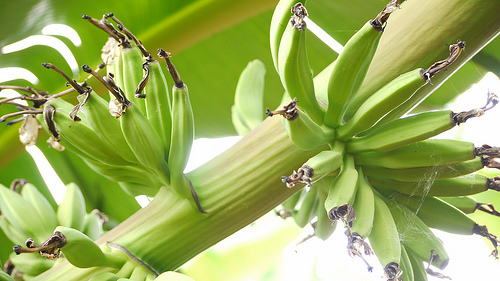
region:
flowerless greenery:
[0, 8, 204, 209]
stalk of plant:
[147, 118, 289, 274]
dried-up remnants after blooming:
[415, 36, 466, 96]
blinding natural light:
[210, 215, 345, 279]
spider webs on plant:
[377, 149, 481, 256]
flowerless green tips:
[35, 44, 203, 211]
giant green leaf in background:
[0, 2, 493, 138]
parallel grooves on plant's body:
[222, 151, 265, 207]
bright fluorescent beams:
[0, 16, 99, 113]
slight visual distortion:
[0, 0, 110, 38]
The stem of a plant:
[6, 0, 491, 261]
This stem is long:
[21, 20, 496, 269]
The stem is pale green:
[21, 3, 485, 250]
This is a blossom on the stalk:
[268, 2, 491, 277]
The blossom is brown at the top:
[428, 40, 468, 77]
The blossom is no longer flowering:
[283, 1, 495, 269]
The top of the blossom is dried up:
[429, 36, 464, 77]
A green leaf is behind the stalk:
[3, 2, 494, 153]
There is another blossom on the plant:
[2, 12, 188, 199]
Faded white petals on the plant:
[21, 113, 47, 144]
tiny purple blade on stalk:
[76, 10, 91, 24]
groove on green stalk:
[228, 169, 240, 181]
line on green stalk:
[123, 251, 152, 269]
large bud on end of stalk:
[422, 41, 474, 81]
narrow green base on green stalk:
[324, 96, 356, 133]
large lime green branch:
[158, 11, 243, 48]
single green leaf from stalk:
[221, 58, 281, 130]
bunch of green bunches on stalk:
[253, 8, 453, 137]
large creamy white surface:
[204, 250, 320, 278]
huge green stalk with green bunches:
[73, 13, 472, 243]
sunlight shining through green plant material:
[4, 3, 495, 279]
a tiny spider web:
[372, 134, 457, 236]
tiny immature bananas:
[268, 100, 355, 228]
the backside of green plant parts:
[226, 55, 267, 137]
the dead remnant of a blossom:
[425, 34, 465, 81]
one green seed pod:
[155, 45, 200, 191]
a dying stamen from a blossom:
[12, 233, 68, 253]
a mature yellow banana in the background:
[187, 215, 304, 279]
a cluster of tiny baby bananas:
[9, 11, 194, 184]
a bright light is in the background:
[215, 66, 494, 279]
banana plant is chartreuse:
[1, 0, 499, 279]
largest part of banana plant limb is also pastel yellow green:
[258, 1, 499, 177]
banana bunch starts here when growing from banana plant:
[183, 172, 213, 217]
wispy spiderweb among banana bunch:
[376, 165, 448, 246]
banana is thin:
[336, 37, 471, 144]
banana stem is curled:
[103, 135, 162, 213]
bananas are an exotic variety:
[6, 10, 222, 218]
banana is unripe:
[278, 146, 343, 191]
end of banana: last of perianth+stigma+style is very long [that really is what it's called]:
[416, 35, 473, 86]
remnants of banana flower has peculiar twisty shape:
[131, 60, 156, 102]